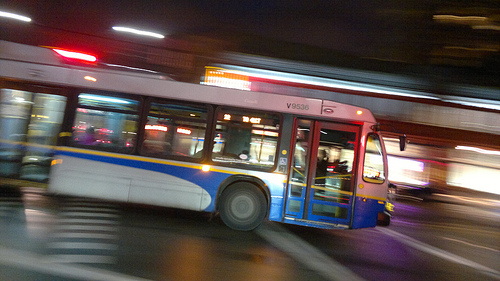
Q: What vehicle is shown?
A: Bus.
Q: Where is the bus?
A: Street.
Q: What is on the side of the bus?
A: Windows.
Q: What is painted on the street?
A: White lines.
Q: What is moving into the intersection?
A: The city bus.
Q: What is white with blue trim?
A: The bus.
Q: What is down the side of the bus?
A: The yellow stripe.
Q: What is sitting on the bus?
A: The people.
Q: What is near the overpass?
A: The bus.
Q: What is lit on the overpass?
A: The lights.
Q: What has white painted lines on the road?
A: The intersection.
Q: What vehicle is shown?
A: Bus.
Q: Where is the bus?
A: Street.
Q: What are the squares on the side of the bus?
A: Windows.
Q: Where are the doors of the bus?
A: Front and middle.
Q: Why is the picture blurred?
A: Movement.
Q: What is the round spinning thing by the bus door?
A: Tire.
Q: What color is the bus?
A: Blue and white.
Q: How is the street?
A: Wet.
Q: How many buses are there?
A: One.